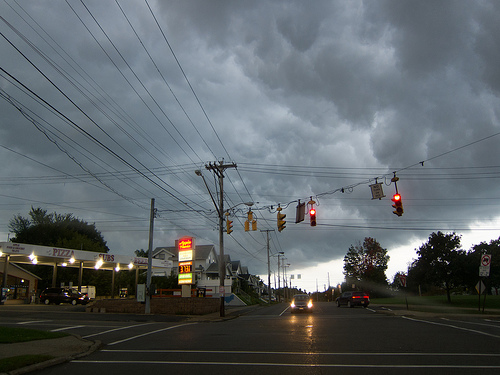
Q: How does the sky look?
A: Stormy.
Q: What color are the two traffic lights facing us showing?
A: Red.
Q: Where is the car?
A: On the road.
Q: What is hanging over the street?
A: Electrical wires.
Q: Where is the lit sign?
A: Hanging from a building.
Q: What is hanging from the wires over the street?
A: Traffic lights.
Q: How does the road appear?
A: Wet.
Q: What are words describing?
A: Food.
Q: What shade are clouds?
A: Dark.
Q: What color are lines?
A: White.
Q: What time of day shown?
A: Dusk.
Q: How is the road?
A: Wet.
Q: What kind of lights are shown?
A: Traffic.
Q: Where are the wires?
A: On pole.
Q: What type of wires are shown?
A: Electrical.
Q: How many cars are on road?
A: Two.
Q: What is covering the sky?
A: Dark clouds.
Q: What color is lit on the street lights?
A: Red.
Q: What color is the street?
A: Black.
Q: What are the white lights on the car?
A: Headlights.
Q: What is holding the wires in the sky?
A: Electrical poles.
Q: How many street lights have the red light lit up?
A: 2.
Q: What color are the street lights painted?
A: Yellow.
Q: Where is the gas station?
A: On the corner.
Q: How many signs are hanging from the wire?
A: Two.